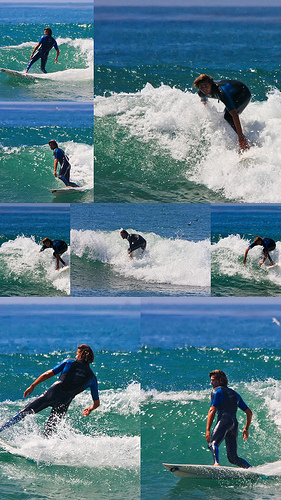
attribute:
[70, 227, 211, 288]
wave — crashing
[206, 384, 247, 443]
wetsuit — black, blue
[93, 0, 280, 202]
water — ocean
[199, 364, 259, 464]
he — wet